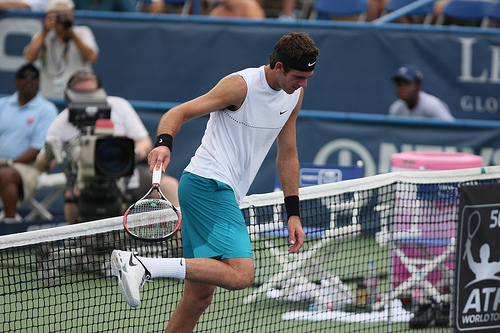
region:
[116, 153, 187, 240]
A tennis racket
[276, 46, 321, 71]
A black sports headband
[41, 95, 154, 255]
A camera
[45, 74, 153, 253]
Man operating a camera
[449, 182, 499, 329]
A sign on a tennis net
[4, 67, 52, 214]
Man sitting in a chair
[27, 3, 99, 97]
Man taking a picture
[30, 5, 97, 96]
Man holding a camera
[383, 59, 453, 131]
Person behind a barrier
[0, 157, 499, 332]
Black and white tennis net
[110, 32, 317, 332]
A tennis player on a tennis court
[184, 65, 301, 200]
White vest tshirt the player is wearing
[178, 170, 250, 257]
Green shorts of the player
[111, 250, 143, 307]
White Nike shoes of the man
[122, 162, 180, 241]
White and orange tennis racket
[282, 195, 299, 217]
Black wristband the player is wearing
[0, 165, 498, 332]
Tennis net dividing the court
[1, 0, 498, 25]
Stands for the spectators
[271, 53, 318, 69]
Black bandana on the player's forehead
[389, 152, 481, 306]
A large pink water cooler.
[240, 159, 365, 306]
A blue and white folding chair.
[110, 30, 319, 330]
A man playing tennis.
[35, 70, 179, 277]
A man operating a camera.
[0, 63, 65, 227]
A seated man watching the tennis player.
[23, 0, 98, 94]
A man taking a picture.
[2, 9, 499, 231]
Two blue barriers between the court and stands.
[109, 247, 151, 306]
The Nike logo is on the shoe.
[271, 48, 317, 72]
A black headband with the Nike logo.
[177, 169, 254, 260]
The shorts are drenched in sweat.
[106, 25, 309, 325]
A tennis player swings the racket.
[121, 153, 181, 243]
The tennis racket is held by the man.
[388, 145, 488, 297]
A pink bucket sits on the sidelines.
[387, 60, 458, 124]
A man sits on the sidelines.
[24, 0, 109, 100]
A man takes a picture.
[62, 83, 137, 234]
A man films the match.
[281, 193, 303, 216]
The wristband on the man's wrist.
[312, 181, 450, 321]
The tennis net.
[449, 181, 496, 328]
The flag is sitting by the net.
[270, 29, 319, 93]
The head band.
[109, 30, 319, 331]
A man wearing white and teal.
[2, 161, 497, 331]
A black mesh tennis net.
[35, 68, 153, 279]
A video camera operator.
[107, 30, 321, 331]
A man holding a tennis racquet.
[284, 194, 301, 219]
A black wrist band.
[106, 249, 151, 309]
A white tennis shoe with a black check.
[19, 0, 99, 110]
A man holding a camera.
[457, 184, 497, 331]
A black sign with white lettering.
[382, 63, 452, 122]
A man in white wearing a blue cap.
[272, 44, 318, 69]
A black sweat band with a white check.